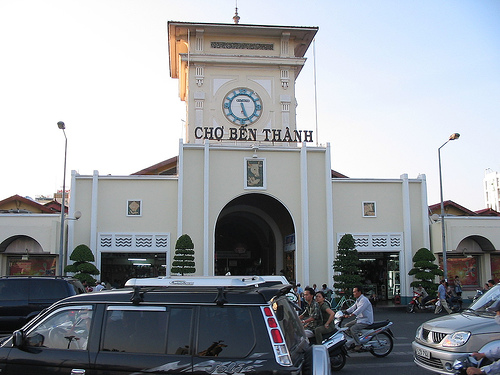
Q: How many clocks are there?
A: 1.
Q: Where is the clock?
A: On top of the building.